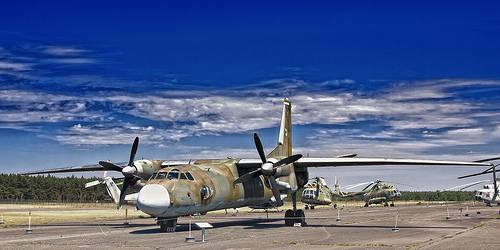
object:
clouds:
[30, 122, 193, 145]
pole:
[394, 210, 397, 227]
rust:
[142, 178, 174, 192]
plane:
[19, 97, 492, 232]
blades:
[232, 132, 303, 206]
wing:
[235, 158, 492, 171]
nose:
[138, 183, 168, 214]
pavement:
[0, 203, 499, 250]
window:
[155, 172, 166, 180]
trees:
[0, 173, 96, 202]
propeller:
[99, 137, 149, 210]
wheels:
[284, 208, 293, 226]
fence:
[0, 197, 107, 209]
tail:
[266, 100, 291, 159]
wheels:
[164, 227, 171, 232]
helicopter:
[300, 175, 338, 210]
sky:
[0, 0, 499, 193]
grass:
[0, 201, 150, 226]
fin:
[333, 152, 357, 158]